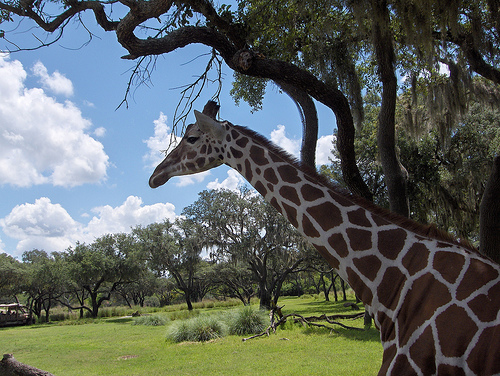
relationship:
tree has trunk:
[314, 1, 427, 231] [371, 41, 411, 222]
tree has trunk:
[0, 1, 500, 321] [279, 64, 379, 214]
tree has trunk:
[0, 1, 500, 321] [275, 76, 320, 172]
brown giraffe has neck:
[148, 101, 500, 375] [225, 116, 407, 328]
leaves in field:
[2, 219, 172, 295] [0, 282, 384, 372]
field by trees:
[0, 282, 384, 372] [0, 2, 499, 317]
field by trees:
[0, 0, 500, 376] [0, 188, 310, 322]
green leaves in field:
[164, 305, 266, 342] [0, 0, 500, 376]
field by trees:
[0, 282, 384, 372] [3, 185, 317, 341]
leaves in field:
[226, 233, 258, 258] [0, 282, 384, 372]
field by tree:
[0, 282, 384, 372] [182, 189, 331, 313]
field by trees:
[0, 282, 384, 372] [43, 241, 429, 309]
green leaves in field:
[60, 247, 146, 272] [0, 282, 384, 372]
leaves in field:
[408, 105, 444, 153] [0, 282, 384, 372]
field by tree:
[0, 282, 384, 372] [335, 70, 498, 260]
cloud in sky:
[0, 0, 347, 259] [2, 1, 499, 269]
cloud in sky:
[211, 165, 263, 214] [2, 1, 499, 269]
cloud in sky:
[0, 0, 347, 259] [11, 51, 117, 226]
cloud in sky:
[0, 0, 347, 259] [2, 5, 489, 83]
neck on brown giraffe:
[249, 141, 459, 308] [148, 101, 500, 375]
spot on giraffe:
[244, 140, 273, 166] [160, 107, 491, 349]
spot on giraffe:
[264, 166, 283, 185] [160, 107, 491, 349]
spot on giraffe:
[304, 184, 329, 204] [160, 107, 491, 349]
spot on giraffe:
[342, 205, 372, 230] [160, 107, 491, 349]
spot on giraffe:
[403, 238, 435, 277] [160, 107, 491, 349]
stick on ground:
[307, 319, 339, 336] [1, 286, 383, 373]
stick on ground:
[302, 307, 367, 321] [1, 286, 383, 373]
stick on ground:
[318, 309, 368, 333] [1, 286, 383, 373]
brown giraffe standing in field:
[148, 101, 500, 375] [10, 306, 373, 374]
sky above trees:
[348, 43, 423, 94] [13, 2, 498, 241]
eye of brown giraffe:
[184, 133, 203, 149] [148, 101, 500, 375]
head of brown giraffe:
[147, 100, 228, 189] [148, 101, 500, 375]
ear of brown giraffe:
[201, 97, 221, 121] [148, 101, 500, 375]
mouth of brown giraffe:
[146, 171, 167, 188] [148, 101, 500, 375]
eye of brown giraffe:
[186, 136, 200, 145] [148, 101, 500, 375]